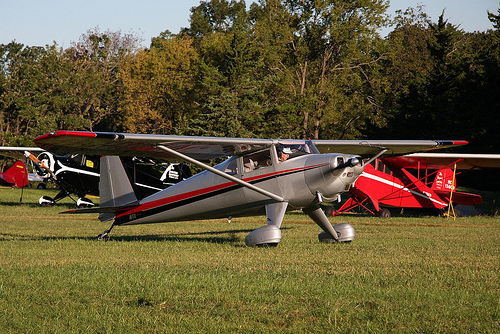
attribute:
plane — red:
[318, 124, 477, 227]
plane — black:
[105, 112, 420, 218]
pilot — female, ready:
[277, 142, 299, 164]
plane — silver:
[39, 62, 462, 271]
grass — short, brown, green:
[0, 240, 498, 332]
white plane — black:
[31, 126, 469, 248]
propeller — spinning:
[320, 147, 382, 199]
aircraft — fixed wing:
[31, 107, 468, 270]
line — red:
[106, 156, 330, 216]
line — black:
[114, 171, 340, 224]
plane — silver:
[81, 115, 366, 272]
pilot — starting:
[279, 144, 297, 169]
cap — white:
[282, 146, 292, 154]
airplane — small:
[33, 101, 480, 273]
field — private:
[1, 0, 498, 333]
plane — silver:
[27, 109, 484, 271]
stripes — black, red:
[110, 159, 332, 229]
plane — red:
[358, 147, 475, 222]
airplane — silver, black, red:
[22, 139, 487, 236]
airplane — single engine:
[28, 130, 468, 248]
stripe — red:
[116, 161, 329, 225]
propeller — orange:
[18, 148, 58, 181]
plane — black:
[17, 149, 192, 210]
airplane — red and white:
[333, 152, 483, 223]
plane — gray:
[26, 129, 468, 249]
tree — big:
[161, 10, 468, 118]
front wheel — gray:
[245, 222, 283, 249]